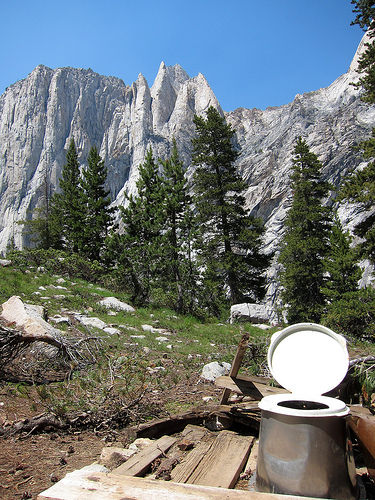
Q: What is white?
A: A toilet.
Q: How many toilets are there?
A: One.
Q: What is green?
A: Grass.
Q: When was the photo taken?
A: Daytime.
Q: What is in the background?
A: Mountains.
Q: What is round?
A: The toilet.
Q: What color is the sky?
A: Blue.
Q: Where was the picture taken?
A: In the mountains.